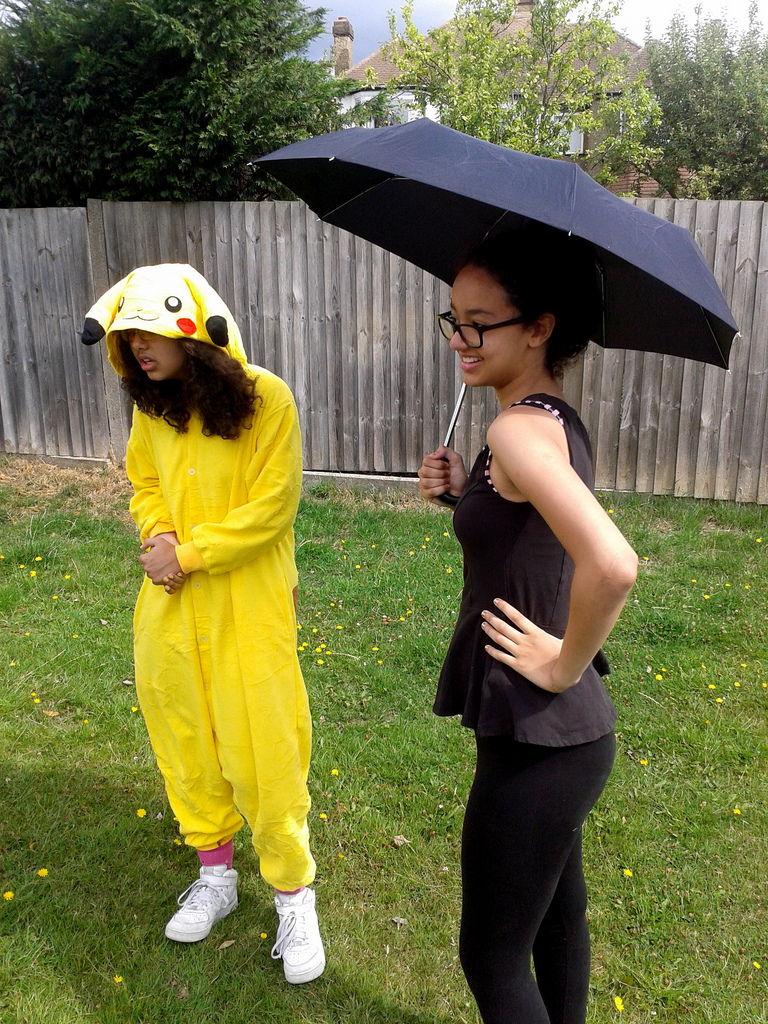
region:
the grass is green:
[58, 868, 173, 912]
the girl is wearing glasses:
[398, 277, 599, 484]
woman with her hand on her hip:
[480, 582, 608, 710]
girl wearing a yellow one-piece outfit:
[76, 267, 327, 884]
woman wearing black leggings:
[459, 713, 623, 1022]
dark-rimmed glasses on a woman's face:
[428, 308, 544, 354]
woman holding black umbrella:
[326, 174, 730, 457]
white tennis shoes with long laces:
[165, 861, 344, 984]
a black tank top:
[434, 398, 628, 740]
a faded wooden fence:
[12, 198, 766, 503]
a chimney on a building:
[329, 14, 357, 82]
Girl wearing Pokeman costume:
[64, 261, 310, 767]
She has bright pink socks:
[164, 833, 346, 903]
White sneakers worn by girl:
[174, 864, 333, 981]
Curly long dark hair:
[117, 332, 266, 443]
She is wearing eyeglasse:
[402, 298, 586, 373]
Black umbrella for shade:
[298, 127, 729, 332]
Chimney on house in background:
[322, 8, 606, 122]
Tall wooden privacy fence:
[5, 205, 111, 462]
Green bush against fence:
[40, 11, 272, 175]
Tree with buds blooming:
[415, 9, 669, 136]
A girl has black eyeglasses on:
[400, 254, 572, 414]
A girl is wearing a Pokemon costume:
[57, 239, 351, 966]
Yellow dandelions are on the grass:
[305, 554, 411, 726]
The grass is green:
[38, 622, 90, 674]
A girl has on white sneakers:
[152, 836, 355, 1001]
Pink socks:
[165, 830, 255, 895]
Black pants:
[430, 693, 647, 953]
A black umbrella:
[235, 83, 755, 441]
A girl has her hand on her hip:
[368, 320, 663, 760]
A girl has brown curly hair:
[77, 263, 305, 457]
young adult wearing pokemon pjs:
[78, 258, 330, 981]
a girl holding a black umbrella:
[251, 106, 738, 522]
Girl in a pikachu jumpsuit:
[83, 239, 326, 953]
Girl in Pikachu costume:
[78, 259, 327, 984]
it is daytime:
[1, 369, 748, 1008]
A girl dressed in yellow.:
[64, 256, 376, 940]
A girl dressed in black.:
[388, 250, 682, 1018]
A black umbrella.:
[263, 96, 766, 332]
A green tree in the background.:
[4, 5, 348, 199]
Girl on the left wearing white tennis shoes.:
[150, 818, 372, 999]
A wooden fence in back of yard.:
[0, 200, 105, 451]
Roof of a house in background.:
[349, 2, 688, 165]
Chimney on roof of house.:
[329, 15, 363, 98]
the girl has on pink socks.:
[142, 810, 348, 903]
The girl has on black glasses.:
[402, 228, 635, 425]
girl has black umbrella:
[271, 144, 607, 282]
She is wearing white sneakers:
[150, 870, 342, 986]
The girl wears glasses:
[417, 321, 494, 364]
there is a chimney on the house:
[336, 9, 351, 69]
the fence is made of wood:
[37, 205, 331, 274]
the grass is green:
[619, 871, 727, 1004]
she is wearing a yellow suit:
[131, 404, 294, 837]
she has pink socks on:
[197, 838, 235, 869]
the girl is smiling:
[431, 285, 492, 395]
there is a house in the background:
[369, 4, 632, 152]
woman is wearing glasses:
[409, 262, 551, 401]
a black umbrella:
[288, 77, 747, 214]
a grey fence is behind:
[279, 233, 388, 337]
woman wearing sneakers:
[269, 898, 353, 1001]